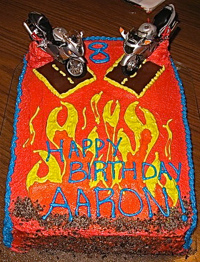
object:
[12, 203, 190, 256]
stuff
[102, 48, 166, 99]
road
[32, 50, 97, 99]
road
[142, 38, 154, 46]
mirrors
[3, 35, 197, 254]
cake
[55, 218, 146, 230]
sprinkles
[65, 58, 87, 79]
front wheel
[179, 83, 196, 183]
icing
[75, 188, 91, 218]
blue a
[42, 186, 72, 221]
blue a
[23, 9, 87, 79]
toy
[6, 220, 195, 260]
cake side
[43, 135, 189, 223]
text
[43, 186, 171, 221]
aaron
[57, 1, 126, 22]
plywood/table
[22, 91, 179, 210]
yellow frosting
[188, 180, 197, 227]
edging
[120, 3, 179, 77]
motorcycle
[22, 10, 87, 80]
bike